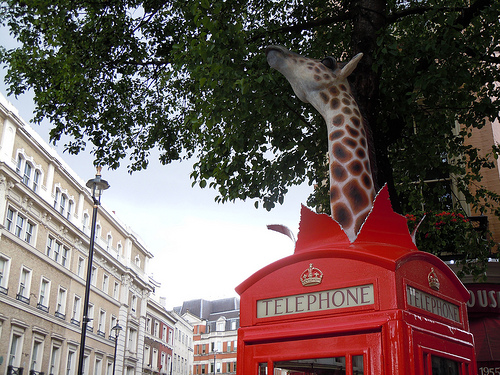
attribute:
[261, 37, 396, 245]
giraffe — eating, reaching, pictured, black, brown, feeding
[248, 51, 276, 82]
leaves — green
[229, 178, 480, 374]
cabin — for phone, broken, red, ripped, telephone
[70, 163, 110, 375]
pole — light, large, black, tall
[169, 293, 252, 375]
buildings — city, red, white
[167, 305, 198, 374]
buildings — city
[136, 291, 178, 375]
buildings — city, red, brick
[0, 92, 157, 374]
buildings — city, beige, white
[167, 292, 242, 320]
roof — black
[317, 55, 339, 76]
eye — large, dark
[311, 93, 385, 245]
neck — long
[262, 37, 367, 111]
head — poking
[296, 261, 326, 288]
crown — gold, golden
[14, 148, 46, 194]
windows — arched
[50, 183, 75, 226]
windows — arched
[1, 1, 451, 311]
sky — pale blue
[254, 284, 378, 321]
telephone — written